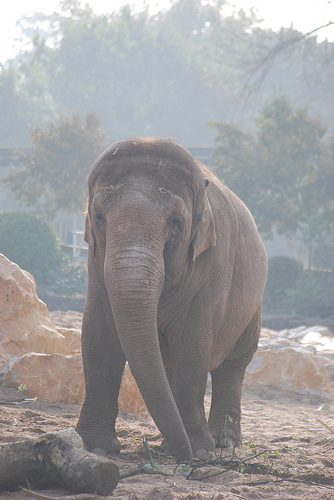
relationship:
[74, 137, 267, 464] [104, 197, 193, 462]
elephant has trunk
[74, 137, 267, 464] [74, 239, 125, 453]
elephant has leg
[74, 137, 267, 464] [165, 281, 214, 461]
elephant has leg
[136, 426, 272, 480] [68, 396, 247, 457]
branches near feet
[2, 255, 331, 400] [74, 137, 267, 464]
rocks behind elephant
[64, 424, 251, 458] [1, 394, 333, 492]
feet in dirt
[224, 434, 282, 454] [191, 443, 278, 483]
leaves on branches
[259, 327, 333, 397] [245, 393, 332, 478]
rocks in sand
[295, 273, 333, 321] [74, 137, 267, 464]
bush behind elephant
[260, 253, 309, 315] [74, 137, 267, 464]
bush behind elephant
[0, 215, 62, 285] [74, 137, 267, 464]
bush behind elephant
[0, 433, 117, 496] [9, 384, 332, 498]
log on ground